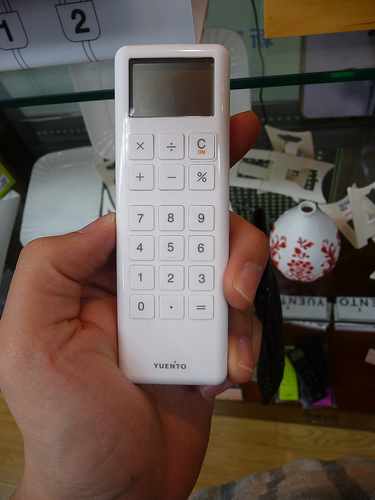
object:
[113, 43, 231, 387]
calculator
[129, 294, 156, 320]
buttons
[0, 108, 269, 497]
hand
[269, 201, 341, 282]
vase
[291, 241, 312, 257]
red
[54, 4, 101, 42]
letters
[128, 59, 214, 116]
screen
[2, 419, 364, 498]
floor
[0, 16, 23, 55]
numbers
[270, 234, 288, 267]
print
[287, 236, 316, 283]
design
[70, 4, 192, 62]
paper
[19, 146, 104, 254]
plate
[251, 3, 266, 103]
cord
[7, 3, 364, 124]
wall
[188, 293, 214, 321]
equal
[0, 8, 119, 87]
text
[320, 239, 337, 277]
patterns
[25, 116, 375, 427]
desk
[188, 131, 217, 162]
button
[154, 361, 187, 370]
yuento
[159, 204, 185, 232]
button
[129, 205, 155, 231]
button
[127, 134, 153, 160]
button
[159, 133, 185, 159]
button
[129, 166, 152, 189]
button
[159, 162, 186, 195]
button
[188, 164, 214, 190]
button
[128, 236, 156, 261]
button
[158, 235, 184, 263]
button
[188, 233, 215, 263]
button